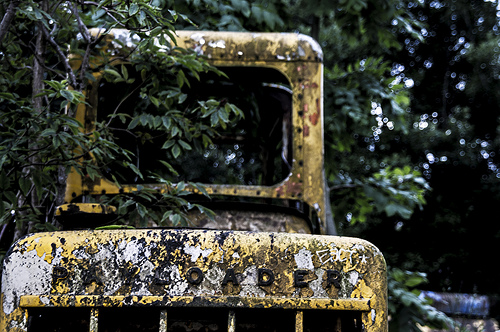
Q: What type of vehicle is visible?
A: Loader.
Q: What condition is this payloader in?
A: Old and rusted.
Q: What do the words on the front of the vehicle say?
A: Payloader.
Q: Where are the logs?
A: On the other side of the payloader.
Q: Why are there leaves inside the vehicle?
A: Because the windshield is gone.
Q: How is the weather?
A: Sunny.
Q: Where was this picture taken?
A: In a forest.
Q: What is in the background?
A: Trees.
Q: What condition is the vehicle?
A: Old and unusable.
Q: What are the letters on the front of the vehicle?
A: PAYLOADER.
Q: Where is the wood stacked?
A: Right side bottom of the image.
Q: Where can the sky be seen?
A: Through the trees.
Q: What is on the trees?
A: Leaves.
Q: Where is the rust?
A: Vehicle.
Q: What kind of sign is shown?
A: Company logo.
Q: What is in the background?
A: Green tree leaves.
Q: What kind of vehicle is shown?
A: A tractor.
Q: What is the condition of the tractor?
A: Rusted.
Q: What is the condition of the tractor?
A: The paint is faded.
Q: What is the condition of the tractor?
A: Abandoned.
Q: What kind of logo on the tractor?
A: Lettering.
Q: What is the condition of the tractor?
A: Broken down.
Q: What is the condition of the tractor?
A: Not working.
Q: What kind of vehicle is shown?
A: Construction.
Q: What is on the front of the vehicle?
A: Missing window.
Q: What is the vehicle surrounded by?
A: Trees.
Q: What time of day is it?
A: Evening.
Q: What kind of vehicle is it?
A: Tractor.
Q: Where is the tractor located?
A: Woods.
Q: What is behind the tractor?
A: Bushes.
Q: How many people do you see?
A: 0.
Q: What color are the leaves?
A: Green.